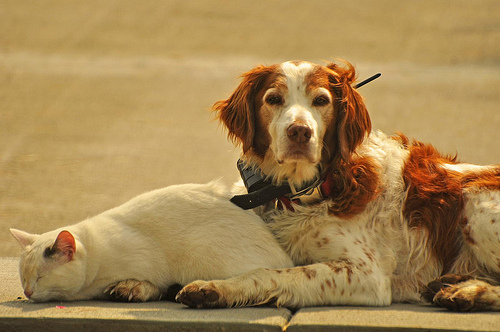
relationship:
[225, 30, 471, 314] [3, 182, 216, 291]
dog beside cat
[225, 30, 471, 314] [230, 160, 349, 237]
dog has collar